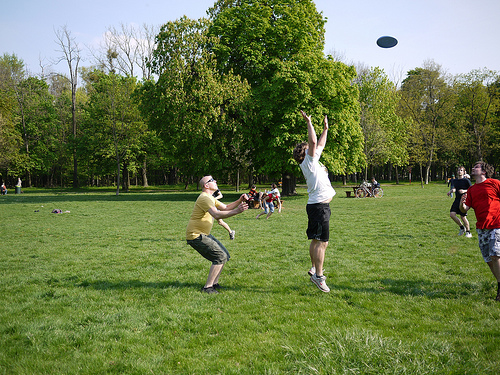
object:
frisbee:
[375, 35, 401, 50]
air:
[0, 0, 500, 373]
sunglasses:
[207, 177, 215, 182]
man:
[299, 108, 337, 293]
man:
[456, 160, 500, 298]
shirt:
[464, 177, 500, 229]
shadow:
[69, 276, 228, 294]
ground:
[0, 179, 500, 375]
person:
[370, 177, 381, 197]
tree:
[46, 19, 85, 189]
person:
[446, 164, 473, 240]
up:
[0, 0, 497, 195]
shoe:
[310, 274, 330, 293]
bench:
[343, 186, 371, 198]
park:
[0, 0, 500, 375]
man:
[183, 174, 250, 295]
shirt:
[183, 192, 218, 241]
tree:
[197, 0, 328, 191]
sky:
[0, 0, 221, 88]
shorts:
[305, 201, 333, 243]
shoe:
[200, 286, 220, 295]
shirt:
[297, 151, 335, 205]